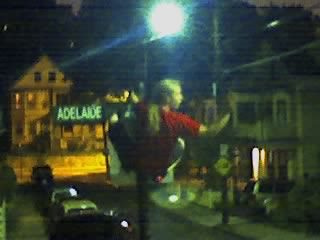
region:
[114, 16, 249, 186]
a man hanging on a lamppost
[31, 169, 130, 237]
several cars lined up along the street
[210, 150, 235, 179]
a yellow caution sign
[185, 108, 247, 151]
the arm of a man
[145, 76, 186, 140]
a man with long hair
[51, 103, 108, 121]
an Adelaida street sign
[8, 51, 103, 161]
the facade of a building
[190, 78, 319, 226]
the facade of a building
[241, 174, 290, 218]
a car parked at a house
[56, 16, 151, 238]
a street signpost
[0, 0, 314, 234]
night scene in a residential neighborhood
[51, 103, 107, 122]
black and white advertising sign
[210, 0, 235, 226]
utility pole with a yellow traffic sign on it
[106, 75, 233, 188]
man with long blond hair and a red tee shirt holding onto two poles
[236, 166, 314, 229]
parked cars at the side of the road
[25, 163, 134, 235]
cars parked at the side of the road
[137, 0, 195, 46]
bright white street light on the side of the road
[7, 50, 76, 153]
white house with some lit windows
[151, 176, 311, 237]
gray cement sidewalk at the side of the road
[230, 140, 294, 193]
outside porch with a light on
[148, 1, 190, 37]
glare from street light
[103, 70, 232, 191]
person climbing light pole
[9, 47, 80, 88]
steep pitched roof on house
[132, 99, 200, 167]
red shirt on climber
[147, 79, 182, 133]
long blonde hair of climber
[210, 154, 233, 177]
street sign on pole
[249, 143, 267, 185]
glare from porch light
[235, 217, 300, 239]
sidewalk beside paved road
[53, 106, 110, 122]
street sign with Adelaide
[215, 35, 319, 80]
power lines on poles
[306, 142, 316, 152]
part of a roof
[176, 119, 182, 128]
part of an arm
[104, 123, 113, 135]
part of a post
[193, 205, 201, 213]
part of a road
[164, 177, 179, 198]
edge of a road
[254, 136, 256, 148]
part of a wall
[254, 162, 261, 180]
part of a light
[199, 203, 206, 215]
part of a road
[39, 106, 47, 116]
part of a window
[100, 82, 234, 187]
this is a person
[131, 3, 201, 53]
this is a light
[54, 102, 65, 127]
this is a letter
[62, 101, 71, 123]
this is a letter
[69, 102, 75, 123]
this is a letter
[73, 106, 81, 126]
this is a letter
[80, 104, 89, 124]
this is a letter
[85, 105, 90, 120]
this is a letter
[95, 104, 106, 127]
this is a letter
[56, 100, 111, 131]
this is a word